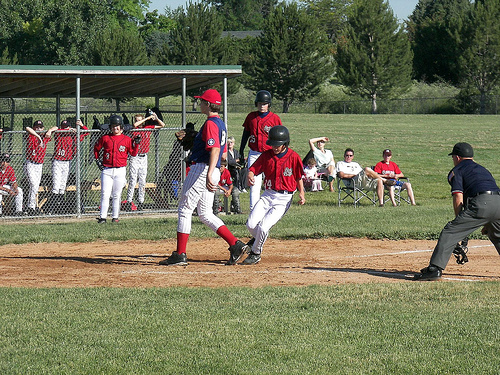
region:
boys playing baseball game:
[10, 31, 482, 344]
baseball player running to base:
[155, 69, 337, 303]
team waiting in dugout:
[5, 53, 200, 235]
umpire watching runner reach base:
[223, 85, 491, 315]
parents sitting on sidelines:
[300, 120, 425, 217]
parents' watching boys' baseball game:
[305, 118, 421, 221]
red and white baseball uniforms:
[164, 74, 325, 303]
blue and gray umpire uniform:
[415, 125, 497, 302]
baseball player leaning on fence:
[12, 105, 64, 212]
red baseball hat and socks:
[159, 79, 251, 285]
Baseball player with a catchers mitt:
[157, 88, 253, 267]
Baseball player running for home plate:
[242, 125, 305, 268]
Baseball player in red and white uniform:
[91, 116, 144, 225]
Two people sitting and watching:
[334, 148, 421, 208]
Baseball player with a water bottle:
[126, 106, 166, 211]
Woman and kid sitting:
[305, 134, 335, 192]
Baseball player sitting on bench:
[0, 153, 26, 217]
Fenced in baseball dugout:
[0, 64, 242, 225]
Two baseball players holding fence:
[23, 114, 89, 221]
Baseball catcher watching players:
[412, 141, 497, 279]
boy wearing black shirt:
[420, 137, 499, 292]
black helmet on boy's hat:
[261, 128, 291, 150]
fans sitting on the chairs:
[302, 137, 434, 207]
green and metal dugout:
[2, 60, 234, 92]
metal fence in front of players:
[12, 133, 60, 210]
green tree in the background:
[336, 53, 401, 115]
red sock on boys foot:
[212, 224, 235, 246]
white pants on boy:
[242, 191, 292, 261]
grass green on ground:
[108, 298, 353, 357]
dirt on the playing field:
[327, 228, 382, 285]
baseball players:
[5, 81, 312, 268]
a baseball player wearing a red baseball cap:
[153, 85, 245, 268]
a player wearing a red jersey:
[241, 123, 312, 268]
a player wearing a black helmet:
[236, 85, 283, 127]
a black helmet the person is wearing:
[263, 124, 292, 149]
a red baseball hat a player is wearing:
[193, 84, 223, 105]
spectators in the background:
[304, 131, 424, 212]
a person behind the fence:
[25, 119, 57, 216]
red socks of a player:
[170, 231, 230, 238]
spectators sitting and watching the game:
[302, 134, 424, 218]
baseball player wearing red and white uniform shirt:
[250, 147, 313, 205]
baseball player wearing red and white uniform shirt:
[98, 129, 134, 170]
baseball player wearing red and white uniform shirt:
[135, 127, 154, 157]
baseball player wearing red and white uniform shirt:
[50, 127, 78, 156]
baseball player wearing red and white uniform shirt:
[23, 134, 54, 160]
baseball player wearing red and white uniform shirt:
[3, 165, 20, 184]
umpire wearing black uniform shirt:
[448, 162, 492, 193]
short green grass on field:
[8, 297, 116, 356]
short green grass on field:
[151, 313, 239, 339]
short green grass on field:
[290, 307, 396, 354]